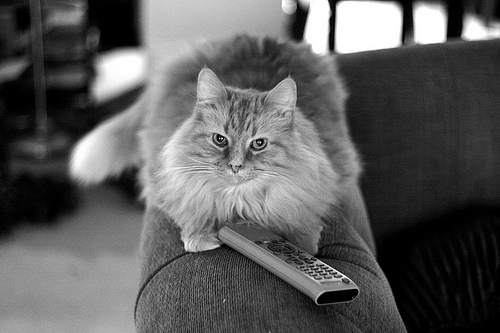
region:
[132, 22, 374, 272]
A long haired cat with a remote control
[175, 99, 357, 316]
A remote control in front of a cat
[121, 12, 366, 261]
Cat is on the back of a chair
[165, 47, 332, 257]
The looks very serious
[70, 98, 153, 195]
The tail of a cat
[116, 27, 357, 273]
Cat on the back of a chair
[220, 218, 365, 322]
A remote control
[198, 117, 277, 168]
The eyes of a cat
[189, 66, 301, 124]
The ears of a cat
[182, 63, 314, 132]
The cats ears stick straight up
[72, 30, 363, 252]
A big fluffy cat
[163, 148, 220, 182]
a lot of cat whiskers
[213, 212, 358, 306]
a tv remote controll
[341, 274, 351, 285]
the power button on the controller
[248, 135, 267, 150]
a cat's left eye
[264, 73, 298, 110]
a cat's left ear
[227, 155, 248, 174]
a cat's nose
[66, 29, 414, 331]
a fluffy cat sitting on a arm rest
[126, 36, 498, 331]
a comfy looking couch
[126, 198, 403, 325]
a part of a sofa arm rest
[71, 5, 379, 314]
a large fluffy cat.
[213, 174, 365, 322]
a remote control on the arm of a couch.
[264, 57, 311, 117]
the left ear of a cat.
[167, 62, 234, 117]
the right ear of a cat.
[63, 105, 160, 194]
the fluffy tail of a cat.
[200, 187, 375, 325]
a remote control.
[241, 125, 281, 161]
the left eye of a cat.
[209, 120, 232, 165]
the right eye of a cat.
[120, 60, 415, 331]
the right arm of a couch.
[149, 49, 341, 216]
A fluffy happy cat.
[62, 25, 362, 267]
The cat is furry.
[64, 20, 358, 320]
Remote control in front of cat.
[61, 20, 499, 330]
The cat is on the arm of the furniture.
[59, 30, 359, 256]
The cat has two ears.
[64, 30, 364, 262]
The cat has two eyes.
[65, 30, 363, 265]
The cat has a tail.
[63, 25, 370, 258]
The cat's eyes are open.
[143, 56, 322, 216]
The cat has whiskers.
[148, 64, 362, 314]
The remote is between cat's front paws.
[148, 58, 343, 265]
The cat has a nose.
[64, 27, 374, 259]
a gray cat is over an armrest of couch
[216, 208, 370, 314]
a remote control in front a cat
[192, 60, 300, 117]
pointy ears of cat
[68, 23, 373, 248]
fur of cat is long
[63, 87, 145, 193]
tail of cat is long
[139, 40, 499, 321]
part of a couch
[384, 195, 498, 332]
cushion on a couch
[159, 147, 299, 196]
whiskers of cat are white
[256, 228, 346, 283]
buttons of a remote control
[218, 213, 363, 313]
remote control is tan